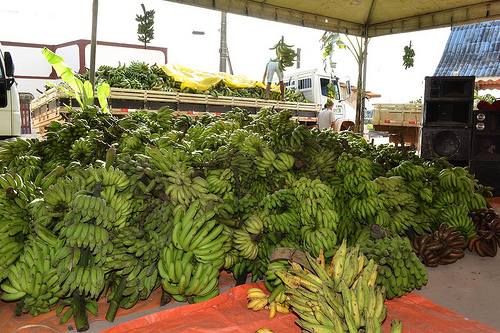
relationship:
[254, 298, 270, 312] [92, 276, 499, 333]
banana on top of sheet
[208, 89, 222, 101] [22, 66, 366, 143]
banana on truck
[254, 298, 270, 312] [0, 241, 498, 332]
banana laying on floor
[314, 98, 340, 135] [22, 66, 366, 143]
person near truck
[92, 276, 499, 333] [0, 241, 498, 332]
sheet on floor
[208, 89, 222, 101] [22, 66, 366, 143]
banana inside of truck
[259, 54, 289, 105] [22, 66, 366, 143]
person on top of truck